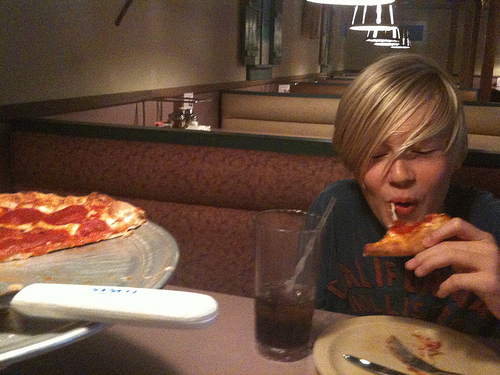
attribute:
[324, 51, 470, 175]
hair — blonde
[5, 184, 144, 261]
pizza — partially eaten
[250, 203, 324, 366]
drink — nearly empty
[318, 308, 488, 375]
plate — paper, round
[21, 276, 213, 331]
handle — white